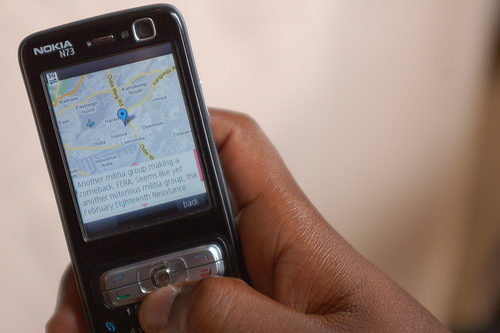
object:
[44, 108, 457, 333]
person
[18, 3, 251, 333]
phone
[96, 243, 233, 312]
keys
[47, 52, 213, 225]
map quest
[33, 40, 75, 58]
nokia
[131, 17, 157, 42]
camera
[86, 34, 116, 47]
speaker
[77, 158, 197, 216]
words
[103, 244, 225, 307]
button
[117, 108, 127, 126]
dot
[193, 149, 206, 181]
line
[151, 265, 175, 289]
silver button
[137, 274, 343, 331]
finger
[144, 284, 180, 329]
nail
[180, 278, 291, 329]
wrinkles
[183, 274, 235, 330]
knuckle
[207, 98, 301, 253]
finger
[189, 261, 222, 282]
red button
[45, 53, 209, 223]
map